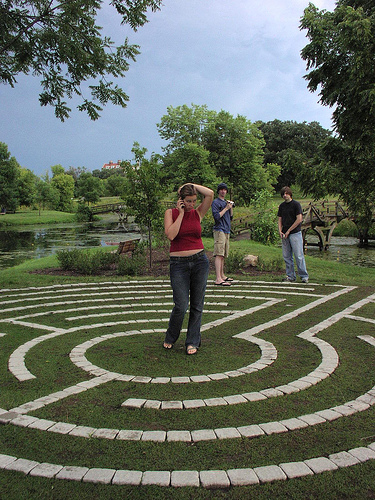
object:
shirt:
[212, 197, 233, 232]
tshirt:
[277, 199, 302, 234]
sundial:
[8, 276, 370, 482]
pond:
[0, 195, 375, 271]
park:
[8, 162, 373, 272]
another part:
[4, 155, 373, 498]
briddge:
[83, 199, 172, 219]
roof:
[104, 161, 121, 165]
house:
[102, 157, 143, 171]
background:
[0, 0, 374, 193]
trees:
[109, 141, 168, 265]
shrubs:
[56, 246, 81, 270]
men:
[212, 182, 312, 282]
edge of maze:
[45, 230, 374, 278]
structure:
[271, 188, 353, 250]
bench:
[117, 237, 139, 254]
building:
[102, 159, 122, 169]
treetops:
[75, 170, 90, 179]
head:
[180, 186, 198, 210]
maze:
[43, 280, 371, 365]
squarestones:
[290, 378, 312, 390]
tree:
[306, 20, 371, 169]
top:
[170, 207, 204, 252]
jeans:
[163, 251, 209, 348]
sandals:
[186, 342, 198, 353]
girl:
[160, 183, 214, 357]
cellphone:
[180, 198, 185, 210]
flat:
[240, 254, 259, 268]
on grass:
[26, 249, 64, 261]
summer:
[163, 338, 175, 350]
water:
[77, 224, 99, 246]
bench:
[300, 200, 346, 249]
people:
[161, 181, 309, 356]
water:
[1, 243, 21, 260]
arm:
[178, 181, 219, 215]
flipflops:
[162, 337, 175, 350]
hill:
[75, 168, 115, 190]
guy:
[211, 181, 235, 285]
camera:
[226, 199, 235, 208]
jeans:
[281, 232, 306, 279]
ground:
[3, 236, 373, 497]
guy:
[278, 185, 309, 286]